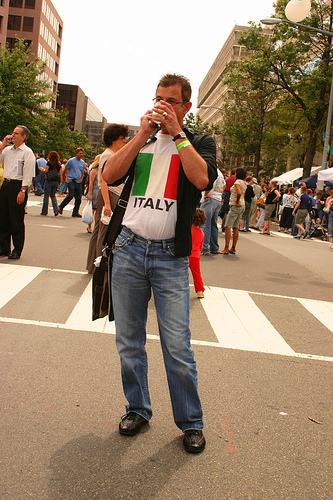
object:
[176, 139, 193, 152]
armband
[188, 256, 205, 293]
pants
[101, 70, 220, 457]
man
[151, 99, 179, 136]
hand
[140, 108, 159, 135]
hand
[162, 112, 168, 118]
ring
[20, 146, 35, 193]
arm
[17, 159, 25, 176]
newspaper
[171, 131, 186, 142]
wrist watch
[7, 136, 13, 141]
cell phone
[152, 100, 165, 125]
cup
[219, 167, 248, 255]
woman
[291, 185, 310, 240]
people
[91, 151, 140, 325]
bag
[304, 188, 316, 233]
stroller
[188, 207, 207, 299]
toddler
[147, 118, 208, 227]
toddler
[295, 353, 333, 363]
white lines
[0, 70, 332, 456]
group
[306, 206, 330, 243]
chair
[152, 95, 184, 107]
glasses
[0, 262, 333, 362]
crosswalk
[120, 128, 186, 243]
shirt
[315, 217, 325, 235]
baby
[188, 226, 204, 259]
shirt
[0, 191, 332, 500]
street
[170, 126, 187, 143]
wrist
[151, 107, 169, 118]
finger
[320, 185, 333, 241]
stroller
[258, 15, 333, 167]
street light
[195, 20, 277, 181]
buildings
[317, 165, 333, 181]
tents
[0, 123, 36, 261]
man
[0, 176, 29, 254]
pants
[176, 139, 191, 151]
bracelet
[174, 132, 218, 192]
arm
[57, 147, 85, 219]
man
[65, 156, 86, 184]
shirt